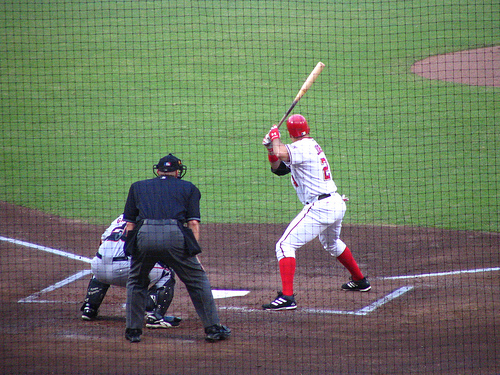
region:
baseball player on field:
[281, 99, 369, 293]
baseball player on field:
[127, 135, 238, 337]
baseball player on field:
[96, 210, 144, 317]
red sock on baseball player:
[270, 253, 296, 298]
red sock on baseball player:
[333, 244, 367, 282]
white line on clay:
[407, 248, 479, 287]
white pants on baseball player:
[285, 198, 350, 256]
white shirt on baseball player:
[280, 141, 333, 208]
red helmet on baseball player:
[287, 110, 313, 139]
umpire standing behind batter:
[125, 153, 230, 343]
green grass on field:
[11, 10, 498, 253]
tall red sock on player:
[271, 250, 307, 293]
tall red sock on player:
[328, 241, 360, 275]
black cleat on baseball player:
[260, 288, 304, 313]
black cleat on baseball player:
[335, 275, 377, 290]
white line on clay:
[411, 259, 465, 282]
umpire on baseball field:
[122, 147, 242, 370]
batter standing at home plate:
[242, 87, 372, 299]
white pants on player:
[279, 199, 351, 248]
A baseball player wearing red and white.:
[259, 114, 375, 314]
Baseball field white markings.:
[384, 267, 498, 320]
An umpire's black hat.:
[152, 152, 189, 179]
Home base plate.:
[208, 284, 255, 299]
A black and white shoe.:
[260, 292, 301, 313]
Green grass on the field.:
[8, 3, 452, 48]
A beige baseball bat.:
[271, 45, 326, 116]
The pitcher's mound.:
[392, 39, 497, 96]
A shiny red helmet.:
[279, 112, 312, 139]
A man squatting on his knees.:
[80, 210, 178, 330]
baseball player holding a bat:
[256, 54, 378, 318]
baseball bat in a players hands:
[260, 57, 327, 148]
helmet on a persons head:
[283, 111, 311, 141]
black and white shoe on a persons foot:
[258, 291, 303, 316]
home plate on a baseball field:
[208, 284, 254, 306]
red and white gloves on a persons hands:
[260, 120, 283, 149]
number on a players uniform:
[317, 155, 333, 185]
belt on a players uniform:
[315, 190, 335, 204]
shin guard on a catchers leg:
[153, 264, 186, 326]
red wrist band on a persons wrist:
[265, 149, 281, 166]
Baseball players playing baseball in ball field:
[68, 53, 378, 347]